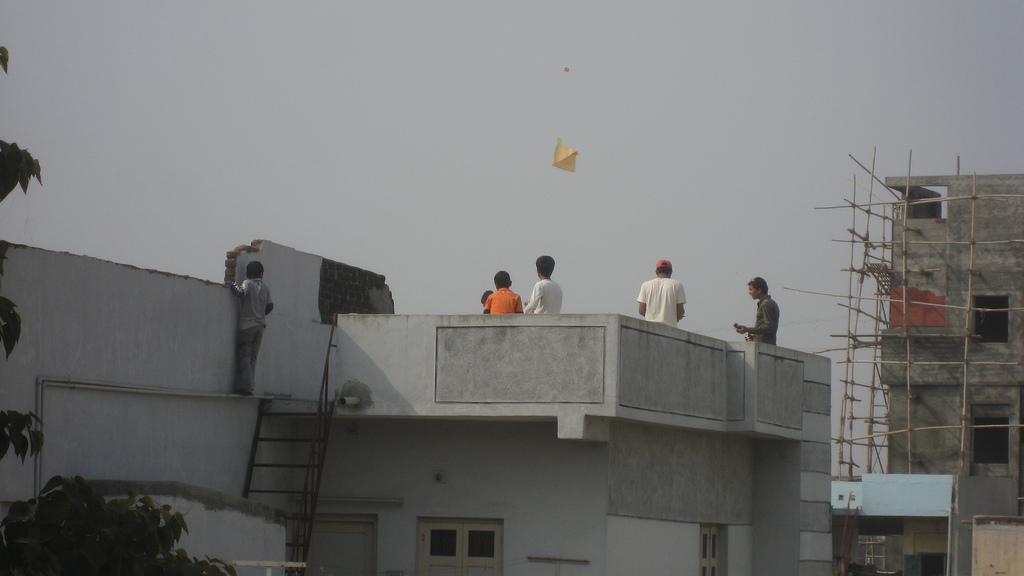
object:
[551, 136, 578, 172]
kite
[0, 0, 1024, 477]
sky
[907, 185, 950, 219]
window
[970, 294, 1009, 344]
window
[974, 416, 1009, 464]
window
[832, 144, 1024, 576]
building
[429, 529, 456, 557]
window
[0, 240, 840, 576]
building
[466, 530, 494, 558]
window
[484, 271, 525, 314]
person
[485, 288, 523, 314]
shirt